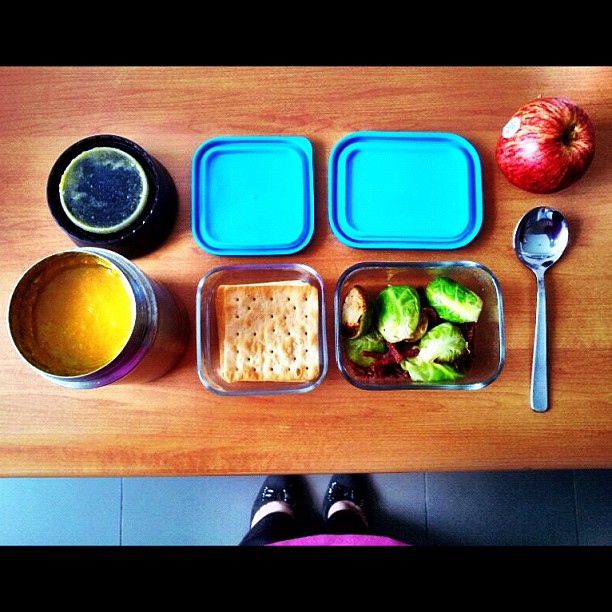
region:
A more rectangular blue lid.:
[328, 131, 484, 252]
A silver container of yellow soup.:
[4, 246, 189, 385]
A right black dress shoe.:
[320, 475, 367, 523]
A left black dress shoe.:
[249, 475, 300, 525]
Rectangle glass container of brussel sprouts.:
[334, 261, 505, 392]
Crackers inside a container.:
[214, 283, 321, 383]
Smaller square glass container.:
[194, 265, 328, 396]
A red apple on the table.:
[493, 94, 597, 198]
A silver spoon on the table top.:
[511, 203, 571, 412]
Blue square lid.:
[187, 137, 313, 256]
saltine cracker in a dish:
[207, 278, 326, 389]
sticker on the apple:
[495, 112, 525, 148]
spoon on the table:
[500, 198, 580, 424]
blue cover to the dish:
[180, 132, 318, 260]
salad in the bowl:
[347, 275, 475, 381]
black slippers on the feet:
[242, 469, 373, 523]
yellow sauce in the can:
[33, 273, 106, 348]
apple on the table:
[485, 118, 596, 194]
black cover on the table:
[45, 128, 180, 248]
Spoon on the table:
[506, 198, 577, 414]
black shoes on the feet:
[231, 464, 377, 533]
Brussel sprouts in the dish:
[332, 256, 509, 395]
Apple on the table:
[494, 81, 597, 200]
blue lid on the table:
[324, 120, 489, 251]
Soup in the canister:
[16, 251, 193, 396]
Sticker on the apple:
[494, 112, 524, 139]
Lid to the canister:
[44, 132, 183, 258]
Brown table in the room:
[0, 65, 610, 475]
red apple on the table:
[493, 91, 597, 189]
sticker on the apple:
[502, 112, 519, 140]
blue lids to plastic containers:
[190, 132, 482, 254]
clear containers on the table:
[189, 259, 504, 412]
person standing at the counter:
[218, 473, 412, 554]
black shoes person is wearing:
[241, 475, 364, 522]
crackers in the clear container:
[211, 278, 310, 381]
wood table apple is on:
[2, 68, 608, 466]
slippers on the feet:
[249, 471, 374, 509]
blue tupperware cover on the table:
[185, 130, 317, 257]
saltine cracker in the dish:
[219, 278, 319, 382]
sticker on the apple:
[499, 106, 525, 149]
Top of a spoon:
[504, 206, 572, 274]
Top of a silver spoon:
[513, 198, 575, 275]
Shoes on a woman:
[246, 476, 376, 530]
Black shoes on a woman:
[250, 475, 375, 530]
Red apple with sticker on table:
[492, 96, 594, 193]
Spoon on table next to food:
[512, 203, 567, 410]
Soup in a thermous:
[6, 245, 186, 388]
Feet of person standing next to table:
[247, 472, 373, 528]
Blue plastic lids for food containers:
[189, 130, 481, 253]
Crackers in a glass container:
[194, 264, 329, 395]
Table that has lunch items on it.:
[3, 67, 608, 466]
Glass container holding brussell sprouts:
[334, 260, 504, 392]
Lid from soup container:
[46, 134, 176, 256]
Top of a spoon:
[511, 204, 572, 277]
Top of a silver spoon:
[505, 205, 573, 274]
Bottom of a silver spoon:
[520, 271, 558, 424]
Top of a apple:
[547, 111, 593, 157]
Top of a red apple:
[552, 118, 588, 153]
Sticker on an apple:
[498, 109, 524, 143]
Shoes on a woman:
[252, 475, 372, 526]